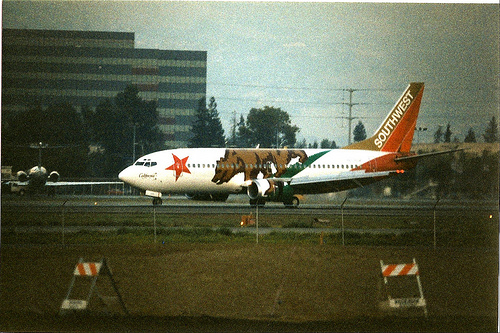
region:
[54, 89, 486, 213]
This is a jet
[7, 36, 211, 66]
This is a floor of a building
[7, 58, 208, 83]
This is a floor of a building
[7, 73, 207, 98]
This is a floor of a building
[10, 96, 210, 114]
This is a floor of a building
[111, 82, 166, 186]
This a big tree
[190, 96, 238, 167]
This a big tree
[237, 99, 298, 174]
This a big tree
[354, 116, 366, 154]
This a big tree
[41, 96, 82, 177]
This a big tree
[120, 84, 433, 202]
white and brown airplane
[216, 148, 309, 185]
brown bear plane decal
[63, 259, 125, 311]
orange and white blockaid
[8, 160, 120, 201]
grey plane on runway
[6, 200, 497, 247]
grey metal chain link fence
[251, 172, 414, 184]
wing on side of plane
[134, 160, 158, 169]
glass cockpit windows of plane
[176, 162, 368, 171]
windows on side of plane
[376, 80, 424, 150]
tail on back of plane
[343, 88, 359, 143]
brown wood electrical pole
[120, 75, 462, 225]
this is a plane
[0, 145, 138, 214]
this is a plane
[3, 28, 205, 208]
this is a building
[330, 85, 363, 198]
this is an electricity pole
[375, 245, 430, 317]
this is a sign post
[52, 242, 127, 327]
this is a sign post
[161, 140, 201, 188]
a star on the a plane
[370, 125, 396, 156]
letters on the plane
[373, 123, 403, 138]
letters on the plane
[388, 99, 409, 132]
letters on the plane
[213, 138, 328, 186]
The California flag brown bear on the side of the plane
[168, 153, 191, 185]
The red five point star near the front of the plane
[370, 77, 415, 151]
The white letters spelling out "Southwest"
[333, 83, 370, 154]
The utility pole with three lines leading from it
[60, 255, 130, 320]
The orange and white barrier on the left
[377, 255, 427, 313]
The orange and white barrier on the right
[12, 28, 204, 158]
The gray and glass office building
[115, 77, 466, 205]
The closest white airplane owned by Southwest airlines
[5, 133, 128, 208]
The white airplane parked to the rear and left of the photo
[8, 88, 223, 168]
The trees immediately in front of the office building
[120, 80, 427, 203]
Plane in the photo.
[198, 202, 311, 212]
A runway in the photo.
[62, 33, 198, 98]
A building in the photo.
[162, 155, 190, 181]
A logo on the plane.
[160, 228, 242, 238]
Green grass in the photo.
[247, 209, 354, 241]
A fence in the photo.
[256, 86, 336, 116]
Power cables in the photo.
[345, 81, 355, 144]
Power poles in the photo.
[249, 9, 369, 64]
Cloudy skies in the photo.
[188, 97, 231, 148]
Tree in the photo.